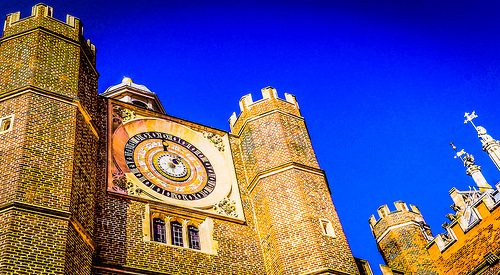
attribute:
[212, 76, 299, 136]
flags — red, white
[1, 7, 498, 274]
building — brown